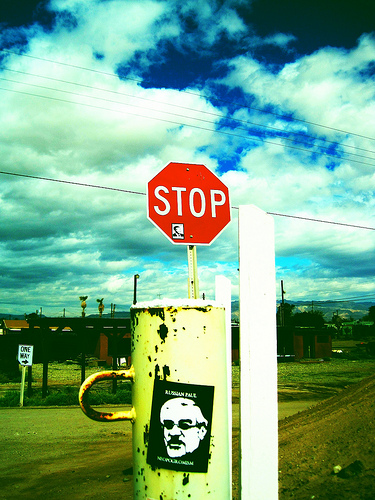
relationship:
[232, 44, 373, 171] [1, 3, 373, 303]
cloud in sky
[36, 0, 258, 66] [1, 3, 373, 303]
cloud in sky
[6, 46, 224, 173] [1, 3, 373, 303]
cloud in sky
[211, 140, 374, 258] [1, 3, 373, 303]
cloud in sky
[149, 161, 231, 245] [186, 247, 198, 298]
sign on pole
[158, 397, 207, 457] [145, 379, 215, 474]
man on poster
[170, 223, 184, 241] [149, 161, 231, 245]
sticker on sign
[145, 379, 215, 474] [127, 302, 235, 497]
poster on post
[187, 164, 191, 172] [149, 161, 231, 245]
screw on sign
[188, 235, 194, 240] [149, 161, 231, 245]
screw on sign